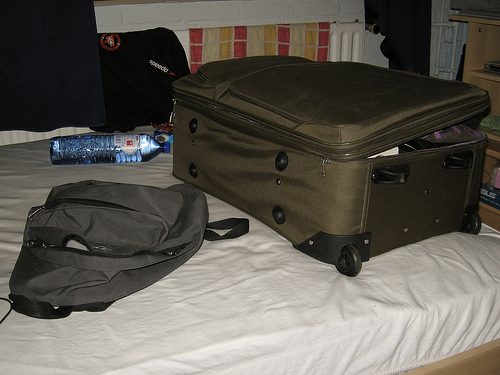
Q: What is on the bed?
A: A water bottle.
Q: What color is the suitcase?
A: Dark green.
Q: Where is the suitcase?
A: On the bed.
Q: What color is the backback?
A: Gray.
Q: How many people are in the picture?
A: None.